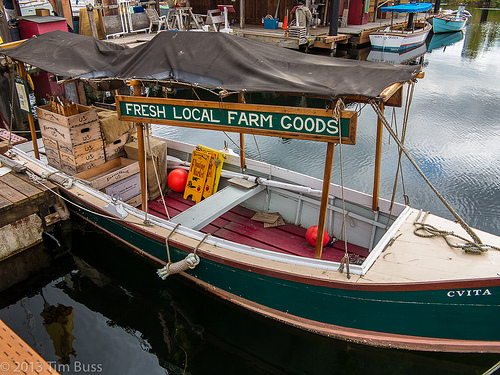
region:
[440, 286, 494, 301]
Cvita boat name on bow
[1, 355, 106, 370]
Name of photograph owner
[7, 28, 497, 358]
Boat dock on water's edge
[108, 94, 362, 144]
Advertisement of goods sold on boat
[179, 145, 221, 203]
Yellow folding street advertisement placards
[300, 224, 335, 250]
Rubber orange boat bumper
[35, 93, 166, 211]
Empty wood crates in boat stern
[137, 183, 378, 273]
Red painted deck of boat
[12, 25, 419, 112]
Tarp overhead protection on boat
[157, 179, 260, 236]
Wooden bench seat on boat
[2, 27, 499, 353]
vegitable market boat by the dock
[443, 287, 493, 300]
name of the boat by the dock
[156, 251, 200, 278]
ropes on the boat hangng on side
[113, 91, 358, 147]
sign hanging on boat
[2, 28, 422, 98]
tarp on top of boat for bad weather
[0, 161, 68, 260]
dock next to boat eith rope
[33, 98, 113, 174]
empty vegitable cartons stacked on boat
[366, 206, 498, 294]
front of boat with rope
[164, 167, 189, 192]
red floating dinggy on boat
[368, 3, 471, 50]
two boats in the background on water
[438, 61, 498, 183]
small river of water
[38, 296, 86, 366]
a person's reflection in water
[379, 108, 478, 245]
a rope on the boat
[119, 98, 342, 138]
wooden sign on boat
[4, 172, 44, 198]
wooden steps on boat dock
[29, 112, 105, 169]
a set of wooden crates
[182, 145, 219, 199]
yellow sign on the boat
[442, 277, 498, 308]
the name of the boat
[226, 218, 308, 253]
red wooden planks in boat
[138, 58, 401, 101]
roof of the boat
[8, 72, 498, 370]
boat pulled at dock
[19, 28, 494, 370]
boat is white and green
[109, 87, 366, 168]
boat has green sign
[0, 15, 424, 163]
boat has overhead tent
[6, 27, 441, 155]
overhead tent is black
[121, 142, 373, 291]
boat has red floor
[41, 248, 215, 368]
water is dark green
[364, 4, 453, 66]
white boat is at dock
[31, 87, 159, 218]
brown crated in back of boat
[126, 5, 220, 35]
white chairs on dock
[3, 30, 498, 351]
boat in dark water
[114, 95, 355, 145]
sign with wooden trim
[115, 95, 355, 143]
sign with white writing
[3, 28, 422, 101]
black canopy on boat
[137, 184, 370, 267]
red floor on boat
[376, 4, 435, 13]
blue canopy on boat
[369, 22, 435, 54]
white boat parked in dark water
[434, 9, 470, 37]
teal boat parked in water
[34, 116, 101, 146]
wooden crate on top of wooden crate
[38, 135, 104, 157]
wooden crate on top of wooden crate